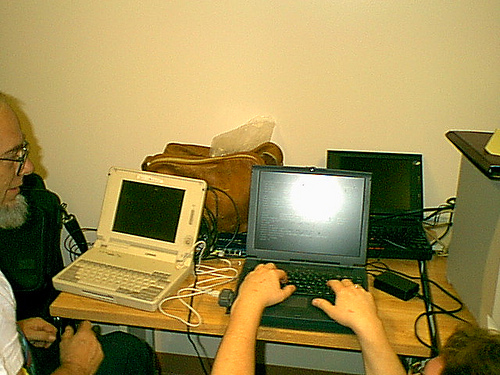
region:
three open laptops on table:
[50, 149, 432, 334]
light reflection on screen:
[288, 174, 349, 224]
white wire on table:
[158, 243, 232, 325]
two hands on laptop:
[211, 263, 391, 373]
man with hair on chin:
[2, 93, 33, 230]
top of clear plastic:
[205, 114, 279, 158]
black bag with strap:
[3, 172, 90, 294]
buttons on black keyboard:
[282, 269, 359, 296]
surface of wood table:
[53, 225, 466, 344]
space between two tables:
[412, 261, 439, 344]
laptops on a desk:
[18, 60, 483, 373]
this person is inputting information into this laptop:
[232, 161, 383, 334]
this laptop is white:
[37, 159, 223, 317]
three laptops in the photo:
[43, 131, 455, 334]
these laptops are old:
[44, 103, 450, 335]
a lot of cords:
[180, 191, 246, 319]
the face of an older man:
[2, 91, 59, 243]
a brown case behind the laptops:
[134, 133, 287, 248]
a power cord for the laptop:
[371, 257, 433, 311]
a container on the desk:
[434, 111, 499, 331]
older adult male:
[0, 90, 158, 374]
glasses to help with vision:
[0, 138, 31, 176]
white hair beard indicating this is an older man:
[0, 197, 32, 229]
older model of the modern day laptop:
[231, 164, 369, 334]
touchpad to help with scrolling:
[278, 292, 310, 309]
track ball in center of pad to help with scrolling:
[368, 234, 378, 243]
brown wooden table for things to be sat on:
[48, 223, 478, 367]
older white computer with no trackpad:
[48, 164, 208, 313]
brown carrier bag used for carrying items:
[143, 140, 284, 175]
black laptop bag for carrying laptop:
[0, 173, 59, 295]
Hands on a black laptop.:
[238, 262, 378, 323]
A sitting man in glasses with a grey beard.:
[0, 94, 162, 374]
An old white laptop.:
[53, 168, 208, 315]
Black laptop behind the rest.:
[324, 147, 432, 262]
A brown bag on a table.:
[138, 140, 285, 237]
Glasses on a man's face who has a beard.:
[1, 143, 28, 177]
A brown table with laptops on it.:
[51, 226, 481, 356]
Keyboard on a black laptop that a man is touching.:
[258, 262, 365, 298]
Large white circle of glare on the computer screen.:
[289, 173, 346, 227]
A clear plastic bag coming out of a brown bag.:
[211, 113, 278, 154]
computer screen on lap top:
[248, 168, 371, 256]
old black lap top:
[237, 172, 372, 331]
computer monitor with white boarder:
[85, 178, 205, 251]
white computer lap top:
[57, 173, 212, 305]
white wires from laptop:
[185, 248, 236, 299]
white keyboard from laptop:
[58, 254, 182, 305]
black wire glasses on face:
[0, 135, 31, 177]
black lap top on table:
[340, 153, 429, 248]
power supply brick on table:
[368, 265, 420, 302]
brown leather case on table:
[152, 136, 273, 196]